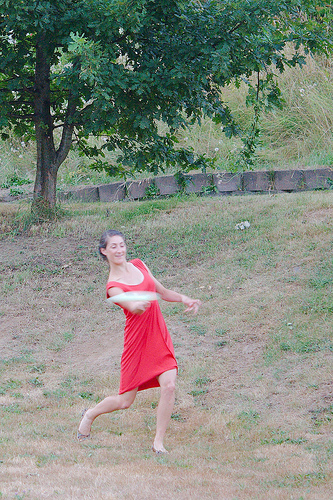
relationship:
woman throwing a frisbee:
[77, 230, 205, 455] [112, 292, 159, 305]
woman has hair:
[77, 230, 205, 455] [97, 224, 124, 260]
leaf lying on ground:
[233, 217, 254, 233] [3, 202, 329, 498]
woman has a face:
[77, 230, 205, 455] [106, 239, 127, 264]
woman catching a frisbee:
[77, 230, 205, 455] [112, 292, 159, 305]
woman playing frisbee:
[77, 230, 205, 455] [112, 292, 159, 305]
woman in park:
[77, 230, 205, 455] [0, 19, 332, 498]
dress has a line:
[104, 257, 179, 394] [131, 303, 154, 388]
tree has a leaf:
[3, 0, 332, 220] [69, 30, 88, 48]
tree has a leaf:
[3, 0, 332, 220] [133, 113, 151, 130]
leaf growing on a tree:
[69, 30, 88, 48] [3, 0, 332, 220]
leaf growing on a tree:
[133, 113, 151, 130] [3, 0, 332, 220]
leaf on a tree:
[261, 40, 277, 52] [3, 0, 332, 220]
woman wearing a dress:
[77, 230, 205, 455] [104, 257, 179, 394]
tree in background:
[3, 0, 332, 220] [0, 0, 330, 266]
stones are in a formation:
[60, 163, 332, 204] [61, 164, 332, 202]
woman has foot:
[77, 230, 205, 455] [70, 406, 105, 440]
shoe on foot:
[74, 411, 99, 445] [70, 406, 105, 440]